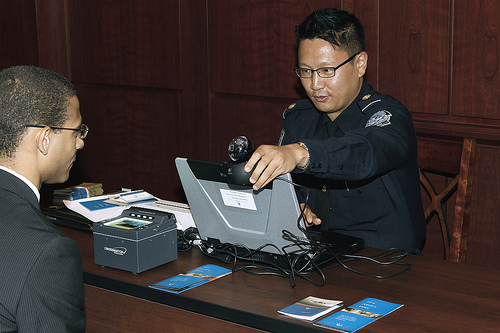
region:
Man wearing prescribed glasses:
[290, 58, 347, 83]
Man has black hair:
[290, 10, 344, 36]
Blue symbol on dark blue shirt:
[352, 108, 402, 129]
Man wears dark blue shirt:
[330, 130, 365, 171]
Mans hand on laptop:
[244, 134, 297, 202]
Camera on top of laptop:
[219, 130, 256, 163]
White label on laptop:
[208, 184, 265, 218]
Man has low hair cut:
[9, 75, 58, 115]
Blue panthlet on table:
[147, 261, 237, 293]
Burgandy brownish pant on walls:
[419, 40, 495, 118]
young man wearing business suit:
[5, 57, 89, 332]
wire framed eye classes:
[33, 111, 94, 151]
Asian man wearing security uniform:
[239, 9, 437, 280]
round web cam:
[207, 117, 274, 201]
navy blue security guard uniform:
[265, 101, 438, 274]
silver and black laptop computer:
[165, 137, 365, 275]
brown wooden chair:
[365, 109, 482, 271]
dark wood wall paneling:
[91, 6, 273, 111]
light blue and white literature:
[268, 276, 401, 323]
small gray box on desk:
[95, 189, 185, 284]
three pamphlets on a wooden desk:
[149, 262, 405, 332]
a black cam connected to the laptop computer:
[217, 134, 257, 188]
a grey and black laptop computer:
[175, 156, 364, 272]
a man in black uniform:
[174, 7, 428, 272]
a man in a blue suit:
[0, 65, 90, 331]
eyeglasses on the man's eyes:
[22, 120, 89, 140]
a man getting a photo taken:
[1, 63, 91, 331]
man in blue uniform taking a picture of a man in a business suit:
[0, 8, 497, 330]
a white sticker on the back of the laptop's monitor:
[219, 188, 256, 211]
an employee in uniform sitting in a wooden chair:
[244, 7, 477, 261]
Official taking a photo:
[219, 6, 436, 279]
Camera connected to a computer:
[168, 129, 333, 277]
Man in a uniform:
[259, 6, 421, 254]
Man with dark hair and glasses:
[256, 10, 426, 277]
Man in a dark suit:
[1, 63, 101, 331]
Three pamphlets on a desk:
[153, 258, 415, 328]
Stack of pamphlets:
[38, 177, 110, 207]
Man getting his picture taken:
[0, 65, 270, 318]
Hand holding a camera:
[210, 127, 315, 195]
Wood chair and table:
[409, 113, 486, 329]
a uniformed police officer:
[238, 5, 423, 255]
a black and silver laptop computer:
[168, 150, 362, 276]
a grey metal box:
[83, 197, 183, 282]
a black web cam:
[224, 133, 263, 191]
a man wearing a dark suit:
[1, 59, 83, 329]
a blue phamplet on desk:
[138, 262, 228, 299]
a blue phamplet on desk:
[273, 293, 341, 320]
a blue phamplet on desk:
[310, 296, 399, 330]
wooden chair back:
[409, 130, 476, 267]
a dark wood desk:
[33, 191, 493, 329]